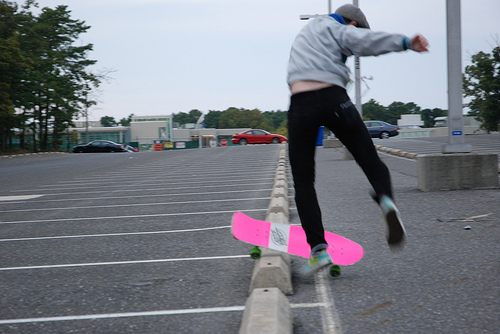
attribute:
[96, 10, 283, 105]
sky — overcast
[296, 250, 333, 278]
shoe — white, small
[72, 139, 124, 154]
car — dark colored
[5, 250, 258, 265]
line — white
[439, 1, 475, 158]
concrete pole — large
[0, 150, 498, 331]
parking lot — empty